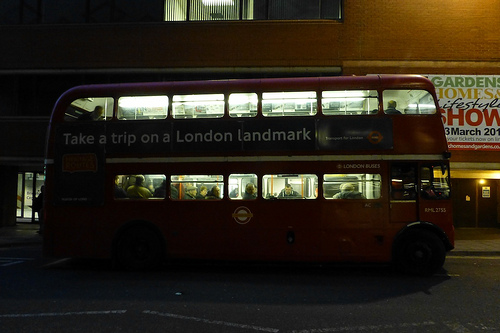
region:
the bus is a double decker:
[68, 83, 450, 300]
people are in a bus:
[121, 173, 357, 205]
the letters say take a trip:
[68, 119, 332, 151]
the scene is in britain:
[0, 50, 497, 331]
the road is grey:
[103, 272, 268, 332]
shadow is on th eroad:
[198, 273, 357, 312]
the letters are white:
[63, 118, 319, 148]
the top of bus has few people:
[102, 93, 377, 128]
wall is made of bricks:
[355, 34, 470, 61]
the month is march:
[446, 122, 498, 144]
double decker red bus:
[45, 93, 477, 284]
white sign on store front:
[412, 67, 497, 122]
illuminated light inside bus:
[87, 82, 464, 137]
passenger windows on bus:
[98, 100, 421, 115]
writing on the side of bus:
[95, 117, 390, 149]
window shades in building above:
[152, 0, 317, 30]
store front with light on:
[441, 175, 499, 227]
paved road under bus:
[34, 262, 487, 332]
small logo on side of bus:
[225, 187, 255, 232]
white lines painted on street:
[32, 292, 189, 329]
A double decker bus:
[23, 68, 475, 295]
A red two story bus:
[23, 67, 497, 332]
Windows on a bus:
[48, 88, 440, 130]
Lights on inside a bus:
[63, 82, 422, 117]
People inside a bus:
[66, 163, 407, 206]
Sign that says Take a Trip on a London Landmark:
[50, 121, 320, 150]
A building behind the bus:
[4, 8, 496, 263]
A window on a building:
[147, 1, 365, 42]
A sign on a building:
[422, 66, 497, 142]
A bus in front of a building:
[3, 63, 495, 330]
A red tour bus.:
[39, 74, 456, 284]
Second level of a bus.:
[42, 73, 451, 161]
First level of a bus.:
[36, 166, 453, 289]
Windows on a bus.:
[59, 88, 437, 118]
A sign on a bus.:
[62, 129, 312, 144]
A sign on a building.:
[418, 71, 499, 148]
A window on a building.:
[164, 0, 251, 21]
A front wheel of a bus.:
[396, 221, 449, 286]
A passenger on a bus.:
[123, 174, 150, 199]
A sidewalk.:
[446, 238, 498, 255]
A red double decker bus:
[39, 69, 458, 287]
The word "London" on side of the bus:
[173, 121, 235, 154]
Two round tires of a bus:
[110, 215, 449, 281]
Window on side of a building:
[161, 1, 259, 28]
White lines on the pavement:
[2, 300, 271, 331]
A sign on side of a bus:
[53, 119, 397, 158]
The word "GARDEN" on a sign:
[431, 69, 497, 92]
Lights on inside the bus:
[61, 85, 438, 200]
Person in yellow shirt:
[123, 163, 153, 201]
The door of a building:
[11, 163, 50, 223]